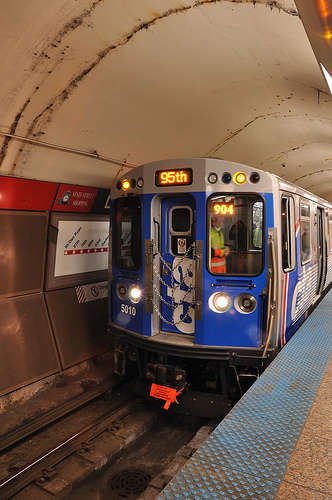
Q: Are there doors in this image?
A: Yes, there is a door.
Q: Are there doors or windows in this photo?
A: Yes, there is a door.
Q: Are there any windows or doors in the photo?
A: Yes, there is a door.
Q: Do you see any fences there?
A: No, there are no fences.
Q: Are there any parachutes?
A: No, there are no parachutes.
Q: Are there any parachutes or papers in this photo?
A: No, there are no parachutes or papers.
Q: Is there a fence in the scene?
A: No, there are no fences.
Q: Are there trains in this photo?
A: Yes, there is a train.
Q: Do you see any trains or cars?
A: Yes, there is a train.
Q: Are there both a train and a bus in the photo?
A: No, there is a train but no buses.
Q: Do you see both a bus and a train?
A: No, there is a train but no buses.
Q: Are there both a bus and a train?
A: No, there is a train but no buses.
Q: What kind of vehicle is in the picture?
A: The vehicle is a train.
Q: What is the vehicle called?
A: The vehicle is a train.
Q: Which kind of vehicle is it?
A: The vehicle is a train.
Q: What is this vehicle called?
A: This is a train.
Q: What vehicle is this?
A: This is a train.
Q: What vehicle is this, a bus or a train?
A: This is a train.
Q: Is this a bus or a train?
A: This is a train.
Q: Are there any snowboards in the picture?
A: No, there are no snowboards.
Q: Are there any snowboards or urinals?
A: No, there are no snowboards or urinals.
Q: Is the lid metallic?
A: Yes, the lid is metallic.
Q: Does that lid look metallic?
A: Yes, the lid is metallic.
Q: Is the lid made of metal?
A: Yes, the lid is made of metal.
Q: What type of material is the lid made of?
A: The lid is made of metal.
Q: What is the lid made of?
A: The lid is made of metal.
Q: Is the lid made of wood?
A: No, the lid is made of metal.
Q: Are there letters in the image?
A: Yes, there are letters.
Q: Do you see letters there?
A: Yes, there are letters.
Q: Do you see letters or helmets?
A: Yes, there are letters.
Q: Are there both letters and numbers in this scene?
A: Yes, there are both letters and numbers.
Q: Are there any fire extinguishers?
A: No, there are no fire extinguishers.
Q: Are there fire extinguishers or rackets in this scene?
A: No, there are no fire extinguishers or rackets.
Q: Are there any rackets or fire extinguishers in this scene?
A: No, there are no fire extinguishers or rackets.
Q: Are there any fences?
A: No, there are no fences.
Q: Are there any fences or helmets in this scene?
A: No, there are no fences or helmets.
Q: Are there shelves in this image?
A: No, there are no shelves.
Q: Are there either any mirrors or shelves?
A: No, there are no shelves or mirrors.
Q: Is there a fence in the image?
A: No, there are no fences.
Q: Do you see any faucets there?
A: No, there are no faucets.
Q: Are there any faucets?
A: No, there are no faucets.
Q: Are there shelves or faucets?
A: No, there are no faucets or shelves.